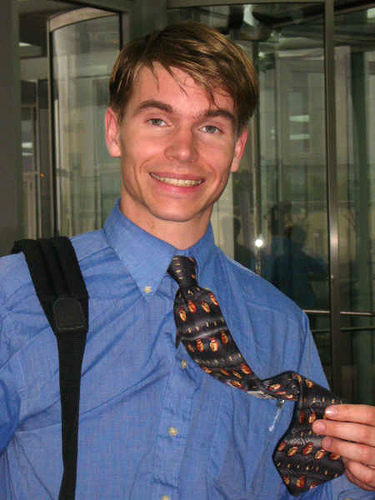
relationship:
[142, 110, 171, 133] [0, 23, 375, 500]
eye of a man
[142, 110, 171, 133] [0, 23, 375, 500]
eye of man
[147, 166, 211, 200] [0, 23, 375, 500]
mouth of man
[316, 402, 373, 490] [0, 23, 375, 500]
hand of man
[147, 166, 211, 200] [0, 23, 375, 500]
smile of man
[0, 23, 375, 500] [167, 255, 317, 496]
man wearing a tie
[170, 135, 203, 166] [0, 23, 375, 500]
nose of man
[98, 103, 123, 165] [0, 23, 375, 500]
ear of man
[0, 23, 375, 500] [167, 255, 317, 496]
man wearing tie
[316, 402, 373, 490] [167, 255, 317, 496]
hand holding tie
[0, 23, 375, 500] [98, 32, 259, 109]
man has hair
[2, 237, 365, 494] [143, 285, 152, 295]
shirt has button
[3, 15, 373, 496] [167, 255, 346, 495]
man with tie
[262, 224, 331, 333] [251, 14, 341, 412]
reflection on window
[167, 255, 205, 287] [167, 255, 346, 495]
knot on tie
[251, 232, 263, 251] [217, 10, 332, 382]
light reflection on window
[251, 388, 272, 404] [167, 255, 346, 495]
brand logo on tie